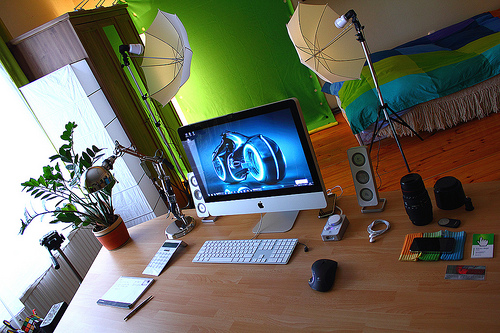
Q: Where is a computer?
A: On a table.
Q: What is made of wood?
A: The table.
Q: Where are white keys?
A: On a keyboard.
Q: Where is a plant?
A: In a pot.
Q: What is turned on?
A: Computer screen.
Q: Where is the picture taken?
A: A bedroom.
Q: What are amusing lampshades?
A: The umbrellas.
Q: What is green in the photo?
A: A wall hanging.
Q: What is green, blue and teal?
A: A bedspread.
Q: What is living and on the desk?
A: A plant.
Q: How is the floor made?
A: Of wood.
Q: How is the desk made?
A: Of wood.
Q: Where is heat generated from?
A: A radiator.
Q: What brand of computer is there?
A: Apple.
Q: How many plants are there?
A: 1.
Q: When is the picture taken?
A: Daytime.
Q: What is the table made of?
A: Wood.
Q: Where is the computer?
A: On the table.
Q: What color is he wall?
A: Green.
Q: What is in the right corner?
A: A bed.